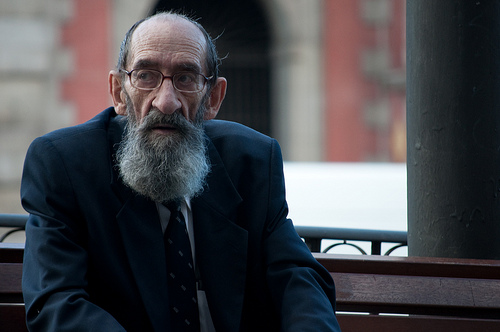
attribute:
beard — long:
[117, 132, 211, 201]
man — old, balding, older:
[20, 13, 341, 331]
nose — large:
[152, 79, 182, 114]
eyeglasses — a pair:
[119, 68, 215, 93]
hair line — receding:
[129, 11, 208, 40]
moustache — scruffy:
[136, 110, 201, 134]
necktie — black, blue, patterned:
[163, 196, 199, 330]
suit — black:
[20, 105, 343, 331]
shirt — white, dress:
[155, 191, 216, 331]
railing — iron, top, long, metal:
[1, 214, 409, 257]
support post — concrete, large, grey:
[405, 0, 499, 322]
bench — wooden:
[0, 241, 499, 331]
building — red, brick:
[0, 1, 408, 243]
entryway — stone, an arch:
[112, 0, 324, 165]